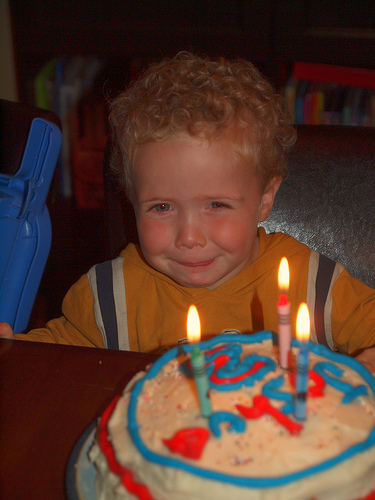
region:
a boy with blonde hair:
[94, 82, 339, 337]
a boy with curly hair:
[84, 50, 300, 271]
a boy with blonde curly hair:
[148, 65, 321, 327]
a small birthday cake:
[89, 294, 367, 498]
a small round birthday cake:
[102, 316, 368, 432]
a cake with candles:
[129, 253, 359, 498]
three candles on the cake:
[132, 286, 328, 496]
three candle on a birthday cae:
[141, 270, 372, 476]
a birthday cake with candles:
[148, 222, 374, 430]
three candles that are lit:
[174, 286, 374, 462]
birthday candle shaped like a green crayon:
[186, 305, 221, 418]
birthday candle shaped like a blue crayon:
[293, 300, 310, 421]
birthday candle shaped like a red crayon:
[271, 248, 294, 366]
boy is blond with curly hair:
[118, 48, 280, 288]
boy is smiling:
[115, 53, 286, 284]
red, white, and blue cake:
[71, 324, 373, 498]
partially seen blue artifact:
[0, 114, 65, 329]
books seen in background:
[255, 32, 373, 127]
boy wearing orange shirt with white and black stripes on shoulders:
[94, 53, 343, 348]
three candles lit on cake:
[181, 255, 320, 431]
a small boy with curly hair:
[77, 40, 280, 286]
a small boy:
[88, 51, 287, 295]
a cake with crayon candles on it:
[161, 292, 344, 498]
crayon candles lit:
[164, 298, 368, 443]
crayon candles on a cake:
[162, 302, 354, 495]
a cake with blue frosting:
[92, 344, 303, 497]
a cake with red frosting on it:
[94, 366, 260, 498]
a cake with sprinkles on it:
[113, 335, 289, 498]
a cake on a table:
[61, 295, 373, 475]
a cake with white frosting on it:
[98, 321, 203, 499]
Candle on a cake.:
[174, 308, 232, 424]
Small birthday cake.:
[53, 304, 372, 488]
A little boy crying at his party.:
[98, 51, 286, 291]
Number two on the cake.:
[192, 341, 270, 392]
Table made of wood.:
[8, 344, 78, 422]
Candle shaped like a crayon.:
[291, 344, 309, 436]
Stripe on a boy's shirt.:
[72, 247, 141, 362]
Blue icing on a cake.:
[139, 441, 170, 472]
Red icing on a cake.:
[95, 436, 135, 496]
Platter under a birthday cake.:
[59, 435, 93, 498]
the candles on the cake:
[191, 294, 309, 419]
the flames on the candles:
[186, 257, 309, 348]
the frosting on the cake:
[87, 329, 374, 499]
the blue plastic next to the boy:
[0, 117, 63, 333]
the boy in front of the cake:
[0, 50, 374, 374]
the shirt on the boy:
[13, 226, 374, 356]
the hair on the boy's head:
[108, 49, 299, 201]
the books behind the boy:
[36, 60, 372, 208]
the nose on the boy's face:
[174, 211, 205, 248]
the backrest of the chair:
[102, 123, 373, 288]